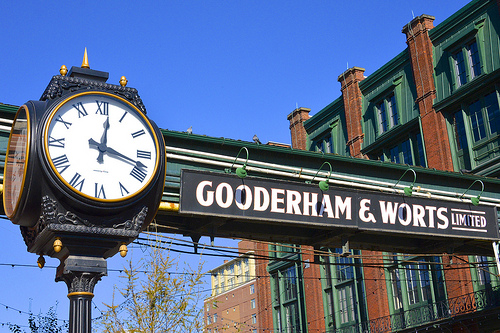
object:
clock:
[35, 89, 165, 210]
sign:
[178, 168, 500, 240]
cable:
[141, 231, 493, 258]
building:
[202, 0, 500, 333]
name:
[195, 180, 489, 233]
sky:
[0, 1, 473, 333]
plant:
[93, 218, 254, 333]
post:
[59, 253, 110, 332]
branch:
[0, 303, 41, 317]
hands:
[88, 137, 149, 169]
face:
[43, 91, 159, 203]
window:
[212, 271, 219, 281]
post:
[81, 45, 91, 69]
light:
[225, 147, 250, 179]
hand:
[97, 116, 111, 162]